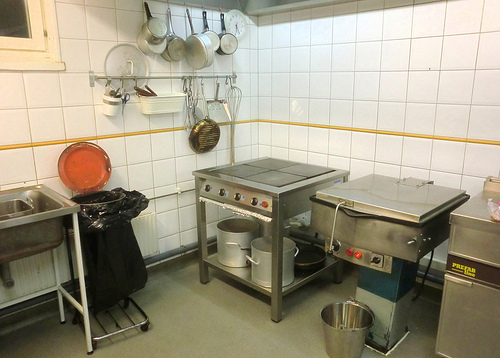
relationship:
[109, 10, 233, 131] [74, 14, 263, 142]
pans on wall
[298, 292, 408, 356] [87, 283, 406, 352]
pail on floor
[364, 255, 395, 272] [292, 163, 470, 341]
knob on stove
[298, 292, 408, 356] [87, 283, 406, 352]
bucket on floor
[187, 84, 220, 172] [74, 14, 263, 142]
skillet on wall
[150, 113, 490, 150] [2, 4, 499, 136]
line on wall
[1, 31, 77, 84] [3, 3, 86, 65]
edge of window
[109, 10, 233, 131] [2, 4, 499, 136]
pans of wall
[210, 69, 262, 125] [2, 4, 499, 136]
whisk of wall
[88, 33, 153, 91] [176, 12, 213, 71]
lid to pot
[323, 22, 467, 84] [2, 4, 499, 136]
tiles of wall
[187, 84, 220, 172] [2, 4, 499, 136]
pan of wall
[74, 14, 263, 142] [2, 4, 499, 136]
wares of wall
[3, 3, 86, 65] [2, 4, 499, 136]
window of wall